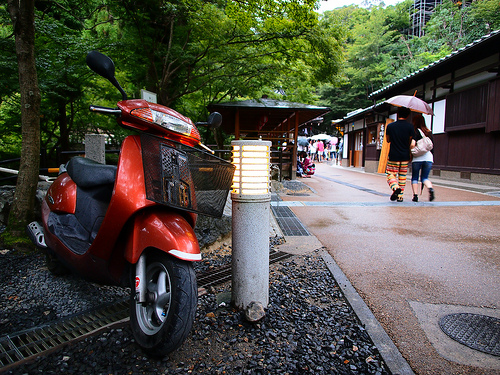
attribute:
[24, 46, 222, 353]
motorcycle — red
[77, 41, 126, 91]
mirror — black, side view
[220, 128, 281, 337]
post — gray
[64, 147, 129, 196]
seat — black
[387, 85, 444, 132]
umbrella — brown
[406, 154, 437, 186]
pants — blue, pair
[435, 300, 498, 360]
grate — metal, sewer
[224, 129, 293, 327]
post — small, lit, light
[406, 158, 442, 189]
jeans — blue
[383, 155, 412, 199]
pants — long, striped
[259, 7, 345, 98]
leaves — green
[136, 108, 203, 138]
headlight — unlit, scooter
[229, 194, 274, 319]
cyclinder — grey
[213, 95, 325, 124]
roof — dark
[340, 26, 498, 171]
buildings — wooden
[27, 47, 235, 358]
motorized scooter — parked, red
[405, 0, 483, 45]
flat building — dark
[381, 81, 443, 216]
couple — open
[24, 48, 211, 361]
orange motorscooter — parked